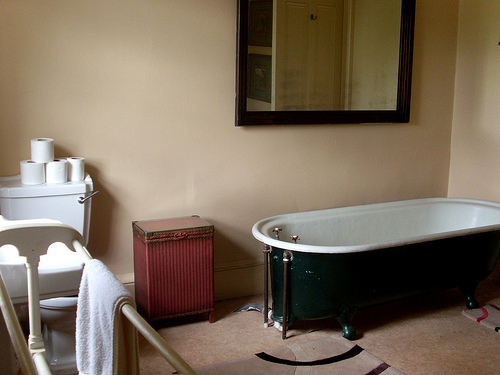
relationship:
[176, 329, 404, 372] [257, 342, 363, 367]
rug with circular lines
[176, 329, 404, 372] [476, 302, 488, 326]
rug with circular lines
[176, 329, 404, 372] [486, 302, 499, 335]
rug with circular lines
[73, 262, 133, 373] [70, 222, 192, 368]
towel on rod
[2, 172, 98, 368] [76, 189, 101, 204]
toilet has handle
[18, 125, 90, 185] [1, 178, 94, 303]
paper on tank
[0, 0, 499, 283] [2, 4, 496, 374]
wall on bathroom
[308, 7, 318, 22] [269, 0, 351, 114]
hook on door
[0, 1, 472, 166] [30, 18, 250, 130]
mirror on wall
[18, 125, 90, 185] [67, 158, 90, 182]
paper on roll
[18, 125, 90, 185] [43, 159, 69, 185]
paper on roll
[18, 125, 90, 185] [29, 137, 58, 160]
paper on roll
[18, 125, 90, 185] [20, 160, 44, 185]
paper on roll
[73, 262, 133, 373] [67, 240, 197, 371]
towel on rack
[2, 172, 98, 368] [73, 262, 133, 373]
toilet and towel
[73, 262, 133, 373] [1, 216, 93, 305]
towel and sink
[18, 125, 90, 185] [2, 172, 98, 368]
paper back toilet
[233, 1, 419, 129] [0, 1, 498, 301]
mirror on wall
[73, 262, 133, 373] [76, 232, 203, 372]
towel on rack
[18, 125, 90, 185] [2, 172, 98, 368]
paper on toilet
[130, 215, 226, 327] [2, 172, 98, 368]
hamper next to toilet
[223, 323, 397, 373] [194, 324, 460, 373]
mat on floor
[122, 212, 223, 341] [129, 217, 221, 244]
hamper has lid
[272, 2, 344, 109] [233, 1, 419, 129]
door in mirror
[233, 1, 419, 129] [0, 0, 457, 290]
mirror on wall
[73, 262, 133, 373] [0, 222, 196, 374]
towel hanging on rack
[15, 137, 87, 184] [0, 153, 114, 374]
rolls sit on toilet